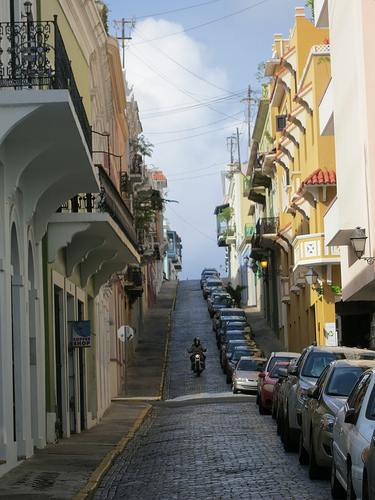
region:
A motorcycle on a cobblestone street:
[178, 324, 212, 388]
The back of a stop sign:
[98, 311, 143, 350]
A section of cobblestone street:
[175, 428, 258, 490]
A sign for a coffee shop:
[61, 311, 100, 362]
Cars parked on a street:
[259, 342, 373, 486]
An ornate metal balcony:
[1, 46, 67, 97]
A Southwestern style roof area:
[280, 166, 343, 204]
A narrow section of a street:
[163, 276, 220, 330]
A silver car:
[225, 350, 270, 399]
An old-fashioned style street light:
[341, 220, 374, 266]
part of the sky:
[230, 22, 271, 47]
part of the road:
[201, 443, 241, 489]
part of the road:
[106, 450, 122, 467]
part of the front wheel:
[308, 457, 324, 483]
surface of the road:
[188, 406, 239, 464]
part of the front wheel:
[194, 360, 204, 378]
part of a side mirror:
[341, 403, 364, 438]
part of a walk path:
[61, 437, 86, 465]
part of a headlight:
[264, 379, 273, 392]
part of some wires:
[163, 42, 205, 74]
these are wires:
[155, 27, 205, 127]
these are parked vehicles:
[229, 326, 367, 439]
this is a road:
[163, 403, 251, 491]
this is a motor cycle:
[182, 332, 215, 387]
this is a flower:
[215, 203, 237, 228]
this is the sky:
[159, 11, 206, 150]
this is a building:
[6, 1, 116, 185]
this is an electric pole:
[109, 13, 140, 61]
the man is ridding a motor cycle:
[182, 327, 214, 363]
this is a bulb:
[256, 257, 275, 274]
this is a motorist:
[184, 333, 207, 377]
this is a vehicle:
[315, 384, 331, 416]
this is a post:
[116, 325, 134, 396]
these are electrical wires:
[157, 70, 172, 82]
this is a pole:
[240, 82, 253, 132]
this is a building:
[274, 121, 314, 283]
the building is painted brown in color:
[299, 151, 320, 164]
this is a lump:
[350, 228, 368, 257]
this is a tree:
[136, 196, 150, 220]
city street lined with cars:
[170, 237, 339, 498]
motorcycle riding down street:
[177, 329, 217, 376]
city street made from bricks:
[158, 278, 283, 492]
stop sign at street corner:
[113, 321, 137, 395]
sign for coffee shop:
[62, 311, 95, 360]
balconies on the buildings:
[55, 64, 134, 257]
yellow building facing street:
[283, 69, 346, 350]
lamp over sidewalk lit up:
[251, 253, 282, 278]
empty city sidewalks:
[35, 279, 168, 484]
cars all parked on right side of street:
[198, 263, 374, 479]